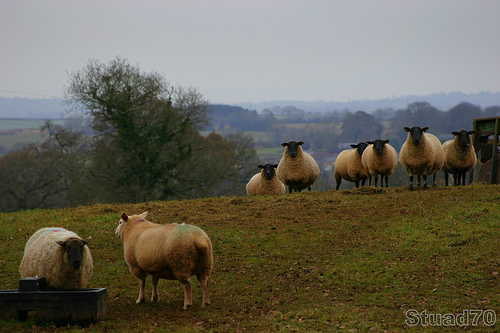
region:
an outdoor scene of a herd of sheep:
[0, 0, 498, 332]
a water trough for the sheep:
[0, 277, 107, 326]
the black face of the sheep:
[55, 234, 95, 269]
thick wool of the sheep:
[398, 125, 445, 190]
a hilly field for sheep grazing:
[217, 183, 499, 332]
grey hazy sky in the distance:
[0, 1, 497, 123]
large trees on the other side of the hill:
[1, 60, 245, 210]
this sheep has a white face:
[112, 211, 212, 311]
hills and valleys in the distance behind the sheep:
[0, 91, 498, 147]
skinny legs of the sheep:
[407, 171, 414, 191]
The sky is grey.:
[3, 3, 496, 140]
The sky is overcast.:
[5, 3, 495, 117]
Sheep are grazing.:
[27, 106, 483, 313]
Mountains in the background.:
[5, 81, 488, 146]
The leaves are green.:
[42, 53, 240, 208]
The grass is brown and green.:
[7, 188, 483, 315]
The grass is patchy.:
[7, 192, 477, 309]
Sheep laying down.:
[15, 212, 112, 306]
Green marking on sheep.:
[165, 217, 208, 241]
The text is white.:
[396, 300, 494, 329]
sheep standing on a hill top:
[208, 104, 493, 223]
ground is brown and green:
[226, 200, 461, 301]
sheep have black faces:
[274, 123, 478, 178]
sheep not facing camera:
[103, 202, 248, 309]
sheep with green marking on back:
[166, 212, 237, 300]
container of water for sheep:
[0, 278, 121, 323]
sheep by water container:
[9, 221, 124, 322]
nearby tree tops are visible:
[24, 62, 227, 203]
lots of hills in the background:
[18, 72, 460, 123]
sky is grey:
[188, 28, 408, 119]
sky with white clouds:
[200, 0, 498, 92]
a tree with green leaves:
[80, 65, 195, 187]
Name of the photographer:
[400, 305, 495, 325]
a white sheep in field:
[116, 208, 218, 308]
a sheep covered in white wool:
[15, 225, 100, 291]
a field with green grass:
[247, 232, 387, 314]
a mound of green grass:
[338, 185, 393, 200]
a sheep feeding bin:
[0, 278, 111, 319]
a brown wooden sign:
[475, 114, 498, 184]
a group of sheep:
[225, 106, 482, 196]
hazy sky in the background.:
[245, 28, 314, 45]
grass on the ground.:
[375, 265, 398, 297]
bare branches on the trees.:
[112, 63, 132, 83]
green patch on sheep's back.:
[177, 219, 199, 231]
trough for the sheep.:
[27, 288, 96, 301]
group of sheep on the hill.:
[327, 132, 435, 182]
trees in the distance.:
[413, 105, 438, 123]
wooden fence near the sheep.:
[477, 119, 498, 165]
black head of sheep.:
[284, 140, 302, 157]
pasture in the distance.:
[3, 120, 34, 133]